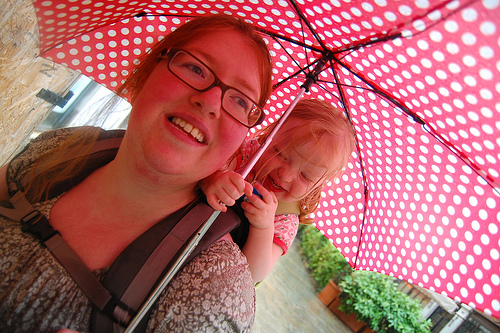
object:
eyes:
[228, 96, 247, 111]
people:
[0, 12, 356, 333]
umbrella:
[29, 0, 500, 333]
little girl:
[196, 98, 356, 289]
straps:
[0, 136, 215, 333]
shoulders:
[29, 125, 127, 154]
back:
[227, 221, 251, 251]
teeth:
[171, 117, 205, 143]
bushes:
[296, 225, 435, 333]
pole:
[118, 87, 306, 333]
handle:
[213, 172, 244, 212]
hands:
[241, 183, 281, 230]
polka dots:
[462, 33, 475, 46]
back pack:
[231, 204, 252, 253]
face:
[255, 120, 344, 203]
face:
[131, 29, 261, 180]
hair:
[11, 11, 272, 225]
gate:
[394, 278, 431, 309]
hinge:
[410, 281, 462, 315]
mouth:
[163, 111, 210, 147]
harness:
[20, 209, 61, 247]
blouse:
[0, 125, 257, 333]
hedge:
[316, 277, 374, 333]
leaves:
[364, 286, 398, 311]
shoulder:
[158, 216, 252, 302]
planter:
[317, 279, 342, 307]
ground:
[246, 245, 357, 333]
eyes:
[179, 64, 205, 80]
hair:
[252, 99, 356, 225]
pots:
[318, 278, 377, 333]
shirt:
[273, 213, 300, 256]